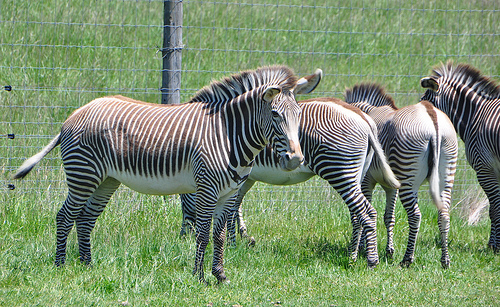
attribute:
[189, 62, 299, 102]
zebra mane — black, white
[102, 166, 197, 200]
belly — white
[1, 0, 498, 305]
grass — long, green, brown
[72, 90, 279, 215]
zebra — white, black, striped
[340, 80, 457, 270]
zebra — striped, black, white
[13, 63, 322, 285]
zebra — striped, black, white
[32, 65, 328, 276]
zebra — black, white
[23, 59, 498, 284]
zebra — striped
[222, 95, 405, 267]
zebra — striped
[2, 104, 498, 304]
grass — long, green, brown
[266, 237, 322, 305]
grass — brown, long, green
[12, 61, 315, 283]
white zebra — black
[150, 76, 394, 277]
zebra — white, black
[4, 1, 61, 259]
fence — wire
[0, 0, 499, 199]
fence — barbed wire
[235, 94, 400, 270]
zebra — striped, black, white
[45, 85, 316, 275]
zebra — black, white, striped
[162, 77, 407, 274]
zebra — black, white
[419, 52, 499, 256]
zebra — black, white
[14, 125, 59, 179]
tail — extended, zebra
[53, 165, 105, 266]
leg — back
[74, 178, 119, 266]
leg — back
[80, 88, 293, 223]
zebra — striped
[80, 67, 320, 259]
zebra — striped